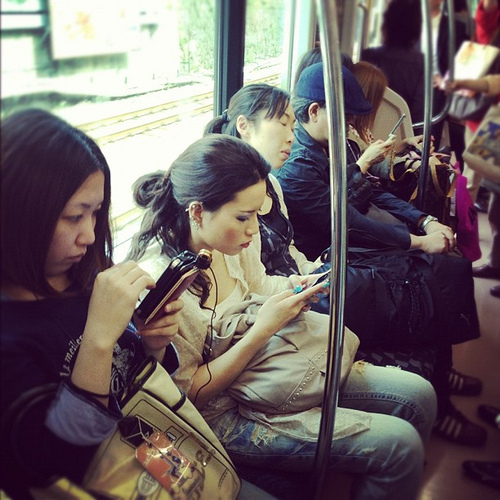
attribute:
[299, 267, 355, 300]
case — silver, black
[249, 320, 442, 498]
jeans — blue, worn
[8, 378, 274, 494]
purse — here, black, beige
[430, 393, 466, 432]
sneakers — striped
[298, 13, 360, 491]
pole — held, metal, steel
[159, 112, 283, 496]
woman — napping, looking, sleeping, asian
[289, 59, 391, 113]
hat — black, blue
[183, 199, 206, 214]
ear — piercved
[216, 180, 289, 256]
face — here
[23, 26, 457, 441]
people — riding, looking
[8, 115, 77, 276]
hair — brown, black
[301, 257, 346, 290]
phone — checked, here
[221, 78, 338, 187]
woman — asleep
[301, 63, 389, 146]
cap — blue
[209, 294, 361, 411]
bag — tan, grey, cream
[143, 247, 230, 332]
cell phone — here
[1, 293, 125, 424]
shirt — black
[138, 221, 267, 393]
shirt — white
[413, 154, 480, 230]
bag — black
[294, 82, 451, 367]
man — sitting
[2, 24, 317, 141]
window — here